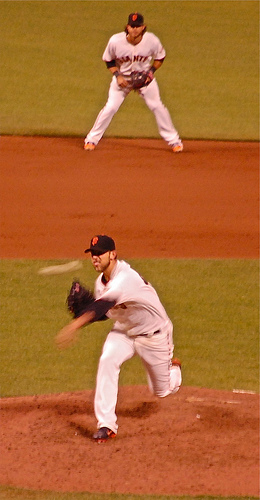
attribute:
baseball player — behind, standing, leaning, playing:
[67, 14, 190, 169]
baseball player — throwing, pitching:
[45, 225, 201, 450]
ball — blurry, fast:
[24, 255, 82, 275]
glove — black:
[67, 285, 86, 314]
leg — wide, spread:
[148, 90, 171, 135]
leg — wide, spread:
[109, 93, 119, 112]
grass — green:
[7, 20, 78, 94]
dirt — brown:
[159, 439, 173, 444]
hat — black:
[128, 14, 141, 25]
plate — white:
[189, 394, 249, 413]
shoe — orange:
[98, 429, 112, 440]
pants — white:
[113, 335, 160, 356]